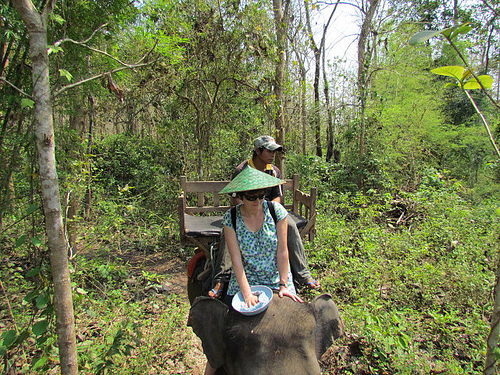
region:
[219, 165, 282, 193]
green asian style woven hat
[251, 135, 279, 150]
gray and black baseball hat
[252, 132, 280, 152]
baseball cap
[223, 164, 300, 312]
woman riding on back of elephant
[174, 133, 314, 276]
young man riding in wooden seat on back of elephant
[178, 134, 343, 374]
two people riding an elephant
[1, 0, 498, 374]
people riding an elephant in the woods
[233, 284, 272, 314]
cloth hat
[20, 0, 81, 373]
tree trunk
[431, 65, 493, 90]
two green leaves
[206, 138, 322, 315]
People riding on elephant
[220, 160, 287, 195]
Green cone shaped hat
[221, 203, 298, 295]
Woman wearing blue top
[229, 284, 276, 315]
Small blue colored hat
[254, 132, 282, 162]
Man wearing green cap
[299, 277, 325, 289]
Man wearing blue slippers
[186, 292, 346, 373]
Gray head of an elephant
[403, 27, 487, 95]
Green leaves on branches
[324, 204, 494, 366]
Green vegetation on ground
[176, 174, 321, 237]
Wooden bench on elephant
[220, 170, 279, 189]
The green hat the lady on the elephant is wearing.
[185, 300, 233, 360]
The left ear of the elephant.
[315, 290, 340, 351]
The right ear of the elephant.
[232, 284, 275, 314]
The bowl the lady is holding on the top of the elephant's head.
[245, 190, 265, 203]
The sunglasses the lady is wearing.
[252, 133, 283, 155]
The hat the guy is wearing.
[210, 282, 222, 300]
The left foot of the guy.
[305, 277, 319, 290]
The right foot of the guy.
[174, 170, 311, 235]
The wooden seating area in the back of the elephant.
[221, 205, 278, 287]
The blue shirt the lady is wearing.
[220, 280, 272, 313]
The bowl the lady's hand is placed in.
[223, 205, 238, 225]
The left strap on the lady's shoulder.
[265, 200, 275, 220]
The right strap on the lady's shoulder.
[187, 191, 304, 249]
The area where the man is sitting.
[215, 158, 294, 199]
Green hat on woman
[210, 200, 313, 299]
Blue and white shirt on woman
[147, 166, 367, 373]
Woman riding on elephant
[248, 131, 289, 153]
Black and grey hat on man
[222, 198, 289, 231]
Black backpack straps on woman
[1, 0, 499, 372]
Two people riding on elephants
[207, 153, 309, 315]
Woman looking at greenery on elephant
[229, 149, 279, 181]
Yellow shirt on man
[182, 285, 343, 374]
Brown elephant head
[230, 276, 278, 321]
Woman holding onto blue handle